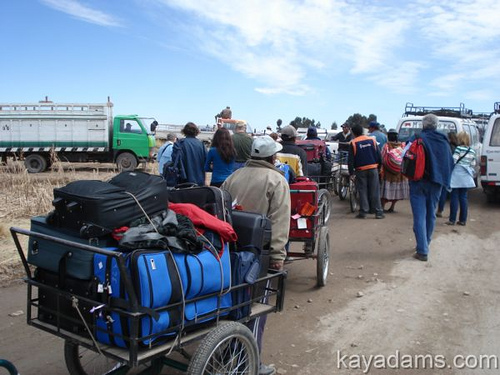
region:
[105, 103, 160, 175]
green truck cab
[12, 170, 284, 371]
luggage in a metal cart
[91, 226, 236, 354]
blue suit case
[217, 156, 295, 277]
a tan jacket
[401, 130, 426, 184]
red and black backpack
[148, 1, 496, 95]
white clouds in a blue sky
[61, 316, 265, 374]
two black tires under the wagon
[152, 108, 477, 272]
a group of people walking down the road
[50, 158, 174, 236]
black luggage strapped down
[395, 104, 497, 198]
two white vans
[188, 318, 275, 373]
black wheel on a cart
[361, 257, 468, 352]
gray and brown dirt road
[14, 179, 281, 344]
black and blue luggage on a cart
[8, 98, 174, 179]
Green and silver truck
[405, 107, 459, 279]
Man carrying a red backpack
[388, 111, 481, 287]
man in a blue jacket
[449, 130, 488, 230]
Woman wearing jeans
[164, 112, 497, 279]
group of people walking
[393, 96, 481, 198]
van parked on a dirt road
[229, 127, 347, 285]
man wearing a white cap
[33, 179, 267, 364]
a cart carrying bags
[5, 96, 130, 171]
a white lorry in the background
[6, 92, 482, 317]
a group of people travelling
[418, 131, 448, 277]
a white guy carrying a bag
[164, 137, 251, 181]
a couple standing together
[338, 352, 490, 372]
a water mark is on the image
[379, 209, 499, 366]
a murrum road is seen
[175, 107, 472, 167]
a group of cars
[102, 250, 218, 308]
a blue suit case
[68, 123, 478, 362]
the weather looks sunny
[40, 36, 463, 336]
people and vehicles on a dirt road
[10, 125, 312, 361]
man pulling cart filled with luggage and clothing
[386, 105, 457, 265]
man walking carrying a backpack over shoulder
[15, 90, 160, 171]
large white truck with green cab being driven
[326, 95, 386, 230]
man standing and leaning left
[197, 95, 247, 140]
man seated on roof of truck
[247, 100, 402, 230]
man facing crowd headed toward his direction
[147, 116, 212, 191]
woman carrying large shoulder bag on her left side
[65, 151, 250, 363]
silver cord keeping belongings tied together on cart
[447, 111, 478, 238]
woman in striped top with dark strap crossing her body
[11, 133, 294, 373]
a man pulls a cart full of luggage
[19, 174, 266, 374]
the cart has a blue suitcase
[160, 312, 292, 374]
a wheel supports the cart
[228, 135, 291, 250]
the man is wearing a beige jacket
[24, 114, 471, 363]
people crowd a busy street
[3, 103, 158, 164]
a green and white construction truck waits on the side of the road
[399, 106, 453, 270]
a man in a blue shirt carries a red backpack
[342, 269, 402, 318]
stones tumble along the dusty road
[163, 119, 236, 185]
a couple wearing blue shirts walk in fron of the cart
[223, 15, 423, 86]
fluffy white clouds float in the bright blue sky